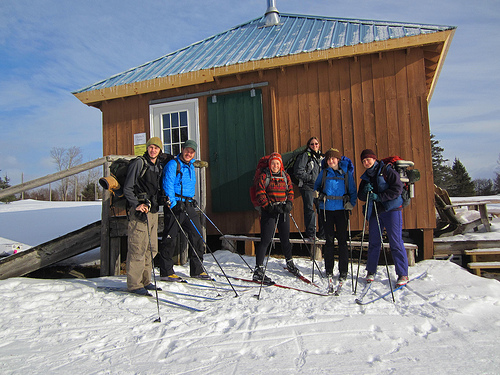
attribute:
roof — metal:
[72, 10, 455, 93]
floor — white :
[245, 308, 314, 357]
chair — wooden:
[434, 184, 482, 231]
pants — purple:
[378, 201, 420, 270]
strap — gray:
[318, 196, 348, 202]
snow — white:
[53, 238, 491, 353]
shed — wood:
[290, 64, 385, 144]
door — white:
[145, 91, 233, 212]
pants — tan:
[124, 202, 164, 300]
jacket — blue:
[163, 153, 195, 209]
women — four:
[251, 134, 398, 258]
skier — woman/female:
[255, 152, 302, 291]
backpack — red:
[252, 160, 273, 200]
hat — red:
[267, 151, 284, 162]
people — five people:
[99, 128, 419, 312]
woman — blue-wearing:
[359, 151, 419, 292]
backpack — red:
[380, 151, 414, 194]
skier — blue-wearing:
[359, 148, 420, 305]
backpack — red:
[378, 153, 420, 187]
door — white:
[146, 106, 198, 154]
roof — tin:
[60, 0, 450, 107]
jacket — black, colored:
[124, 149, 157, 210]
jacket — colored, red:
[259, 180, 294, 205]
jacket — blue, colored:
[163, 157, 201, 207]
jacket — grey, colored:
[296, 152, 318, 189]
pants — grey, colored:
[130, 208, 162, 283]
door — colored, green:
[208, 97, 278, 237]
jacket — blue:
[167, 156, 207, 199]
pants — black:
[178, 212, 219, 262]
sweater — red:
[266, 178, 293, 206]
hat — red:
[262, 145, 288, 166]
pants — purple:
[363, 210, 417, 270]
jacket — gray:
[297, 149, 316, 187]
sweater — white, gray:
[122, 145, 170, 215]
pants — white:
[127, 208, 157, 298]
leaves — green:
[450, 157, 470, 192]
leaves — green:
[81, 180, 97, 194]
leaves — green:
[446, 160, 474, 197]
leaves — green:
[444, 157, 479, 195]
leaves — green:
[444, 160, 482, 200]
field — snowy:
[5, 235, 498, 374]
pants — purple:
[368, 200, 410, 279]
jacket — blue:
[161, 155, 200, 208]